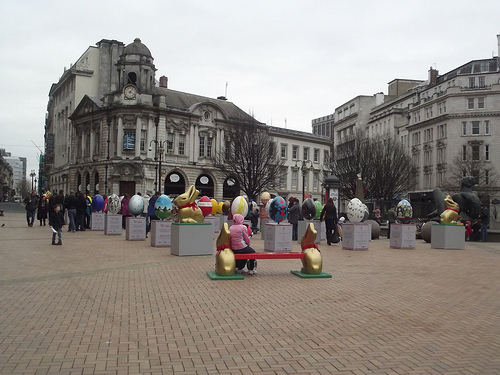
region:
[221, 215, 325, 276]
person in pink jacket sitting on bench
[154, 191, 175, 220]
blue egg with painting on it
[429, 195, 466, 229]
gold bunny on pedestal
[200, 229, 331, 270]
red bench with gold bunnies on the sides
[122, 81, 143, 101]
clock on building in the background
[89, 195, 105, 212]
dark blue egg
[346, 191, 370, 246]
white egg with painting on it on a pedestal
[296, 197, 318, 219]
black painted egg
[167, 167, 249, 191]
three circles in the arches of the building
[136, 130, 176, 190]
streetlamp near building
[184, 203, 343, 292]
Woman sitting cartoonish bench.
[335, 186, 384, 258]
large white egg sculpture.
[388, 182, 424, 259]
colorful egg sculpture.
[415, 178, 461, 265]
golden rabbit sculpture.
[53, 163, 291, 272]
group of colorful egg sculptures.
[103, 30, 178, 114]
tall clock tower on building.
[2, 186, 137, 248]
crowd of people looking at egg sculptures.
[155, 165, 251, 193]
clocks in arch ways of builidings.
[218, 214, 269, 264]
woman wearing a pink hoodie.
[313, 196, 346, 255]
person standing near giant eggs.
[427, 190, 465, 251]
golden easter bunny statue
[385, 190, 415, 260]
painted easter egg statue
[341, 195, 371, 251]
painted easter egg statue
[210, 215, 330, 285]
golden easter bunny bench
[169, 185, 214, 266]
golden eater bunny statue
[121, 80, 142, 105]
clock face atop a building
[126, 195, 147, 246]
painted easter egg statue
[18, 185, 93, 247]
group of people walking in the square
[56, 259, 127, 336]
bricks in a line in the town square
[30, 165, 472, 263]
easter egg statue exhibit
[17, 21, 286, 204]
gray building on street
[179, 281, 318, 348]
many bricks on sidewalk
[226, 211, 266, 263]
pink shirt on girl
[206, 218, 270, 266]
lady on bench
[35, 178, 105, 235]
group of people on sidewalk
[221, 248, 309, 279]
red bench under lady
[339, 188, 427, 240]
statues on a stand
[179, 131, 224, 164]
windows on gray building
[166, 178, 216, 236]
gold bunny on stand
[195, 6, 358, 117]
white sky above buildings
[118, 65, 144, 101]
a clock on building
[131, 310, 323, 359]
a portion of brick sidewalk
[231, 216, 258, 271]
a woman sitting on bench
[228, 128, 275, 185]
several tree branches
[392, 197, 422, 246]
oval shaped egg on structure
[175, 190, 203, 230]
a golden rabbit on gray object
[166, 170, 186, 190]
a window in building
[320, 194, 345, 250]
a person in black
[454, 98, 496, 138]
a section of windows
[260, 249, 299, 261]
portion of the red bench